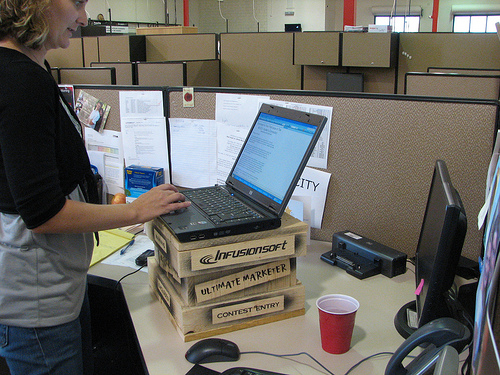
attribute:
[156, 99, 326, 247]
laptop — black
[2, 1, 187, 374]
woman — typing, working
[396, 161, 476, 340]
monitor — black, computer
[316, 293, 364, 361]
cup — disposable, red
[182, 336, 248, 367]
mouse — black, computer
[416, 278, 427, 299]
stick note — pink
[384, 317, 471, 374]
telephone — grey, black, gray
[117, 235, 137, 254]
pen — blue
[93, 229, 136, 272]
notepad — yellow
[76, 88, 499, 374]
desk — office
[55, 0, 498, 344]
cubicles — dark, white, gray, brown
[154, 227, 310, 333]
box — brown, black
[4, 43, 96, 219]
shirt — black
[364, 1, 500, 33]
window — glass, clear